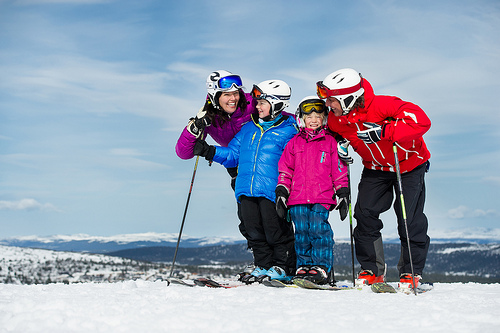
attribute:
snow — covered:
[34, 279, 208, 328]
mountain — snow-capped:
[2, 230, 242, 252]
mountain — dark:
[140, 239, 494, 268]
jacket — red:
[315, 74, 432, 170]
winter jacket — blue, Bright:
[233, 113, 299, 202]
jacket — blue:
[224, 116, 275, 190]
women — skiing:
[317, 68, 429, 294]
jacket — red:
[329, 80, 431, 172]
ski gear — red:
[319, 71, 434, 173]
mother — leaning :
[168, 74, 253, 143]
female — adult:
[176, 68, 251, 180]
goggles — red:
[317, 77, 363, 97]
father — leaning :
[326, 84, 450, 259]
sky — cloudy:
[3, 2, 497, 244]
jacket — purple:
[171, 104, 250, 167]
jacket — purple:
[167, 107, 248, 167]